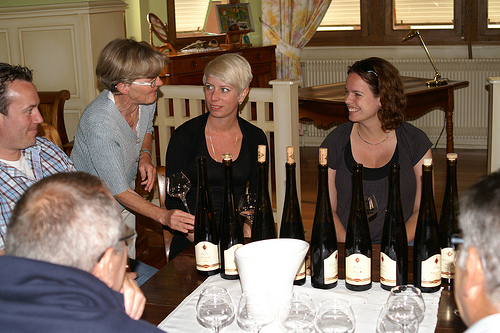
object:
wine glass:
[196, 284, 238, 332]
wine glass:
[282, 294, 320, 333]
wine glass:
[166, 171, 193, 217]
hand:
[161, 208, 195, 233]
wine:
[347, 226, 371, 291]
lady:
[163, 54, 269, 264]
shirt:
[157, 109, 270, 244]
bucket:
[233, 238, 310, 327]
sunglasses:
[358, 59, 379, 81]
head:
[343, 57, 406, 134]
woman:
[308, 56, 438, 282]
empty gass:
[195, 285, 234, 333]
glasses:
[120, 74, 160, 87]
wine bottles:
[192, 144, 460, 293]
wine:
[217, 217, 246, 281]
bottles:
[380, 164, 408, 293]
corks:
[285, 146, 296, 164]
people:
[69, 36, 195, 262]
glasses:
[387, 283, 429, 333]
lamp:
[400, 29, 448, 86]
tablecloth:
[155, 273, 445, 333]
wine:
[194, 205, 221, 277]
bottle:
[344, 163, 373, 290]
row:
[196, 283, 433, 333]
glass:
[372, 300, 424, 333]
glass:
[311, 299, 358, 333]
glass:
[233, 293, 281, 333]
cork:
[317, 147, 329, 165]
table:
[128, 244, 464, 333]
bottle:
[192, 154, 221, 276]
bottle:
[218, 150, 245, 279]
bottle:
[251, 143, 277, 243]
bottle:
[278, 143, 307, 285]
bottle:
[311, 147, 337, 289]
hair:
[344, 56, 408, 135]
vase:
[232, 237, 310, 327]